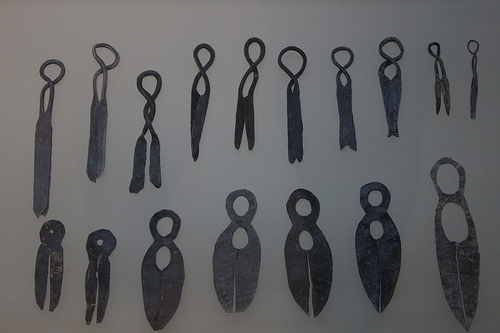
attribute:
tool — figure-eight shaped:
[430, 157, 481, 331]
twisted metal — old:
[127, 68, 172, 201]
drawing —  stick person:
[235, 33, 266, 153]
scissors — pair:
[16, 35, 126, 216]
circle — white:
[221, 177, 288, 247]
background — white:
[5, 19, 488, 316]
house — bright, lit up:
[6, 6, 486, 331]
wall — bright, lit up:
[412, 117, 429, 159]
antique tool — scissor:
[273, 36, 318, 169]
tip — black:
[143, 301, 185, 330]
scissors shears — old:
[18, 37, 238, 209]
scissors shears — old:
[30, 184, 274, 307]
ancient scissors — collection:
[27, 29, 489, 331]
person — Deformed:
[65, 227, 120, 308]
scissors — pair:
[124, 66, 162, 197]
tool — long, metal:
[346, 164, 416, 314]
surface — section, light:
[31, 12, 491, 309]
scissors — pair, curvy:
[232, 37, 269, 154]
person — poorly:
[76, 43, 158, 170]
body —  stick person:
[130, 67, 164, 186]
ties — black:
[74, 75, 447, 185]